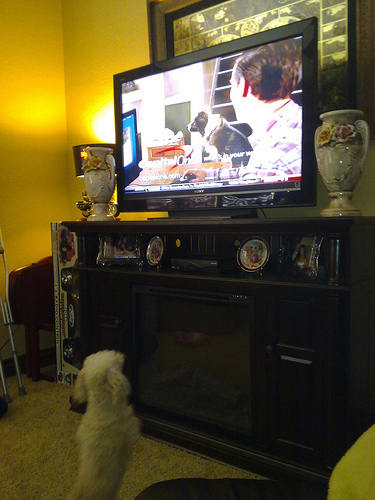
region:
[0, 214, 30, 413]
silver crutches leaning on wall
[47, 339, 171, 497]
small white dog watching television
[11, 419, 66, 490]
light colored carpeting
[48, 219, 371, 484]
dark wooden entertainment center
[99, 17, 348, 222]
large black flat screen television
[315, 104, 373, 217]
decorative vase sitting on entertainment center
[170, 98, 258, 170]
black and white dog on television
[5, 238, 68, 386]
chair in corner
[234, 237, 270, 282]
decorative plate on shelf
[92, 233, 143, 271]
silver framed picture on shelf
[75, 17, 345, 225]
a flat-screen TV on the mantel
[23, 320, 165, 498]
a poodle watching TV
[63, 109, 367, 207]
vases on the mantle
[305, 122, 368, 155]
roses on the vases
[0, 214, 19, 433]
crutches on the wall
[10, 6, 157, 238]
the wall is yellow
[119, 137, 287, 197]
CapitalOne ad on the TV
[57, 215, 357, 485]
a brown wood fireplace mantle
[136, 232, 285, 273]
china on display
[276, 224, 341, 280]
photograph on display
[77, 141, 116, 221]
an ornate vase with sculpted flowers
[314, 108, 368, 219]
an ornate vase with sculpted flowers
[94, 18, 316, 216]
a black flat screen TV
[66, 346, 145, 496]
a small white poodle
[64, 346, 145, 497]
a little dog jumping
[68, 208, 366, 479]
a dark wood TV cabinet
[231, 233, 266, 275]
a small decorative plate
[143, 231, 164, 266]
a small decorative plate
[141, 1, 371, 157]
a framed print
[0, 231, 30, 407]
a pair of metal crutches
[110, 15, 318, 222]
a television set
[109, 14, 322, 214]
the television is on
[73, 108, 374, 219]
two vases are on the cabinet with the television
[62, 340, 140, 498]
a dog is on the floor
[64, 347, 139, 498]
a dog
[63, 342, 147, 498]
a dog watches the television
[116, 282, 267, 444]
a fireplace in a wood cabinet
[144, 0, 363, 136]
a picture hangs on the wall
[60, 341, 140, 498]
a dog is sitting up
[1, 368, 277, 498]
the carpet is beige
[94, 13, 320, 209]
The flat screen TV is black.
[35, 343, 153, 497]
A little white dog near the TV.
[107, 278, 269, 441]
An electronic fireplace.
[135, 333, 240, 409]
Fake logs in the electric fireplace.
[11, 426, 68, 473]
The carpet is white.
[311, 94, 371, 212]
A vase next to the TV.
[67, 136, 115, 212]
A vase on the other side of the TV.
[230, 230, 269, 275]
A decorative plate on a stand.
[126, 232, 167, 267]
Another decorative plate next to it.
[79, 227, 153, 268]
A photograph in a frame.